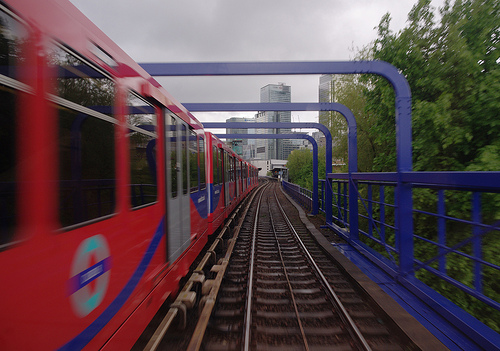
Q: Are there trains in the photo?
A: Yes, there is a train.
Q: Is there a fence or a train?
A: Yes, there is a train.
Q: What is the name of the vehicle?
A: The vehicle is a train.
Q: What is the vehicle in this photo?
A: The vehicle is a train.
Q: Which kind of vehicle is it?
A: The vehicle is a train.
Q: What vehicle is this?
A: This is a train.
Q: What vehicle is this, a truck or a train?
A: This is a train.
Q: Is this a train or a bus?
A: This is a train.